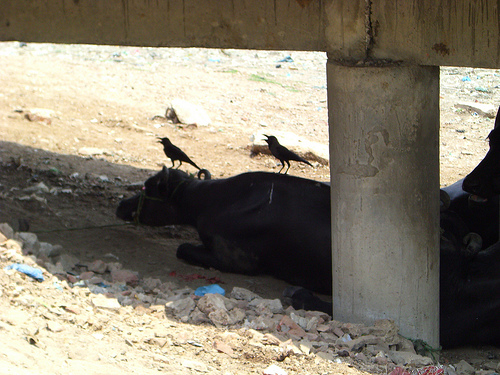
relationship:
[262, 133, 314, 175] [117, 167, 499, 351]
bird on cow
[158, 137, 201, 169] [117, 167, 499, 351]
bird on cow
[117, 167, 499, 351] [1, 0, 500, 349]
cow under bridge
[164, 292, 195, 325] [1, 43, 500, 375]
rock on ground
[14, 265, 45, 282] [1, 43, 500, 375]
rock on ground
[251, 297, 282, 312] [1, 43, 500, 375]
rock on ground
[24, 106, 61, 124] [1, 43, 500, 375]
rock on ground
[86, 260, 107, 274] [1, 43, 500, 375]
rock on ground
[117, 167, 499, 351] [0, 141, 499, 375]
cow in shade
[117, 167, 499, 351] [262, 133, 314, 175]
cow with bird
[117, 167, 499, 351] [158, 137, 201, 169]
cow with bird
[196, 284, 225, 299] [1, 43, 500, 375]
trash on ground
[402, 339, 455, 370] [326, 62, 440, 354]
plant near column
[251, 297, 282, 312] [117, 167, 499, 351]
rock near cow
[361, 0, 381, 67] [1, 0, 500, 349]
crack in bridge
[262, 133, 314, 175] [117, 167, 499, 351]
bird standing on cow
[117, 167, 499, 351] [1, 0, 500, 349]
cow laying under bridge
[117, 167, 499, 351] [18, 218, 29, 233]
cow tied to stake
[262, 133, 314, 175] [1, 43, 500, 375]
bird on ground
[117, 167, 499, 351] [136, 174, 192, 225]
cow has harness